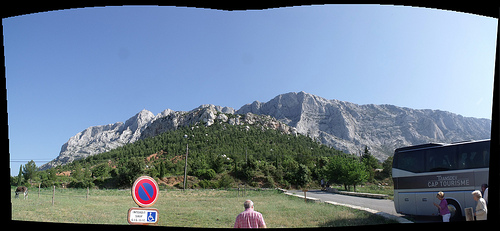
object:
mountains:
[6, 90, 493, 190]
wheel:
[441, 198, 464, 223]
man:
[231, 199, 268, 230]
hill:
[9, 102, 392, 189]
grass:
[160, 190, 232, 225]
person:
[468, 188, 489, 221]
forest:
[10, 110, 391, 194]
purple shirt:
[231, 209, 266, 231]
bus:
[390, 137, 491, 225]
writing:
[417, 175, 487, 189]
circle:
[130, 174, 161, 207]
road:
[279, 186, 405, 222]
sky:
[0, 17, 497, 89]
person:
[428, 190, 455, 227]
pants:
[440, 213, 454, 224]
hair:
[242, 199, 255, 209]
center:
[133, 178, 158, 205]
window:
[390, 148, 427, 176]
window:
[463, 143, 498, 170]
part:
[288, 147, 321, 175]